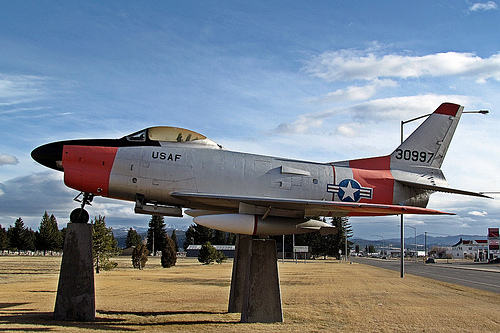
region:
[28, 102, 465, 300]
Jet plane sitting on pillars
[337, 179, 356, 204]
white star in a blue circle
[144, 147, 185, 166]
black words on the side of jet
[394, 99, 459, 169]
numbers on the back wing of jet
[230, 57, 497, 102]
white puffy clouds in the blue sky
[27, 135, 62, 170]
black nose tip of jet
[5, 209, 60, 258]
tall pine trees in the background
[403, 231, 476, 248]
mountains in the background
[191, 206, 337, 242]
missile on the bottom of of jet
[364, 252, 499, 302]
road next to the jet plane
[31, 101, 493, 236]
an US Air Force Jet display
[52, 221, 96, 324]
the concrete display columns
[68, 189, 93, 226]
the jets front landing gear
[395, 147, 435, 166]
the jets identification number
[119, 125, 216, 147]
the pilots cockpit enclosure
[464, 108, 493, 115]
a street light over the street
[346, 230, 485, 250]
mountains in the distance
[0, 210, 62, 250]
pine trees bordering the park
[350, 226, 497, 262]
a small town across the street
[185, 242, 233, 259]
a metal barn in the field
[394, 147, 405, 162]
The number 3 on the tail of the plane.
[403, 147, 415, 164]
The number 0 on the tail of the plane.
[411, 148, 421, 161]
The number 9 on the tail of the plane.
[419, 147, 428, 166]
The number 9 on the tail of the plane.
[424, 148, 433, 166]
The number 7 on the tail of the plane.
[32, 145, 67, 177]
The nose of the plane.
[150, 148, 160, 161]
The letter U on the side of the plane.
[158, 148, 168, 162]
The letter S on the side of the plane.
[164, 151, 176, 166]
The letter A on the side of the plane.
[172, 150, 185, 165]
The letter F on the side of the plane.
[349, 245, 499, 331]
wide and narrow road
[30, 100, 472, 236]
military plane on display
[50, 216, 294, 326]
three cement posts under plane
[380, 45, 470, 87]
white cloud in daytime sky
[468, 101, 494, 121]
light on horizontal post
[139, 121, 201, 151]
dome over plane cockpit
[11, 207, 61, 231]
tops of green trees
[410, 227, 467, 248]
mountain range on horizon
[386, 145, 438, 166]
number on tail of plane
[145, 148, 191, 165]
four letters on plane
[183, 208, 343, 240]
missile with white nose